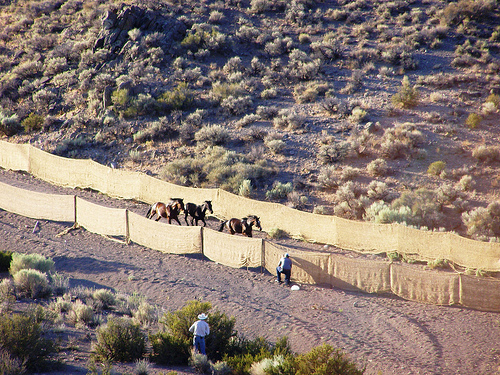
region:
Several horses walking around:
[147, 198, 262, 240]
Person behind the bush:
[183, 308, 211, 353]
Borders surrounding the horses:
[1, 135, 498, 317]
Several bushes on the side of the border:
[0, 297, 362, 374]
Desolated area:
[0, 0, 499, 371]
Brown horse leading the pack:
[219, 213, 262, 244]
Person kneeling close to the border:
[274, 250, 295, 285]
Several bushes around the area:
[0, 0, 499, 242]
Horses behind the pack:
[143, 195, 215, 229]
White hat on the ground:
[289, 280, 303, 292]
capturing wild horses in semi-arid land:
[0, 0, 497, 374]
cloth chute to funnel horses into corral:
[0, 140, 498, 314]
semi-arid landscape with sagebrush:
[0, 2, 498, 372]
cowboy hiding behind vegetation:
[158, 300, 233, 359]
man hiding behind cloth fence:
[275, 251, 293, 282]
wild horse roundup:
[1, 110, 497, 356]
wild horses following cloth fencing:
[3, 140, 499, 314]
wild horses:
[148, 197, 264, 236]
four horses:
[146, 197, 262, 236]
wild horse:
[216, 214, 261, 238]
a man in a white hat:
[183, 308, 219, 362]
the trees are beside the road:
[268, 317, 334, 367]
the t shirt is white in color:
[189, 318, 212, 333]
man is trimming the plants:
[173, 299, 246, 372]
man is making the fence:
[274, 253, 315, 281]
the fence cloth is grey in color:
[328, 256, 390, 298]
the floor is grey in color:
[378, 294, 469, 352]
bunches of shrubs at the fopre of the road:
[222, 60, 274, 117]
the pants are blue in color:
[189, 331, 204, 347]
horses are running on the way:
[133, 183, 255, 236]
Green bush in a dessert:
[96, 315, 149, 374]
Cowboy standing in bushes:
[186, 308, 221, 368]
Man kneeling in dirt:
[272, 253, 298, 295]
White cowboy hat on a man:
[189, 308, 209, 322]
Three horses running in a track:
[135, 190, 270, 242]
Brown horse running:
[223, 209, 260, 239]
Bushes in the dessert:
[168, 53, 393, 189]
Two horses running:
[136, 190, 222, 231]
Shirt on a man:
[188, 315, 210, 337]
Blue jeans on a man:
[193, 333, 208, 357]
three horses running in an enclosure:
[144, 190, 259, 242]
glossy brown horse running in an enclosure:
[144, 192, 192, 227]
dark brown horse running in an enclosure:
[182, 200, 219, 227]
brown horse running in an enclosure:
[221, 213, 273, 242]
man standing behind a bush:
[189, 311, 216, 353]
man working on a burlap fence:
[271, 252, 301, 289]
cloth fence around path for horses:
[2, 138, 499, 338]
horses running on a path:
[143, 190, 275, 248]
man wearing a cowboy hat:
[183, 308, 215, 360]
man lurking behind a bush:
[187, 311, 213, 355]